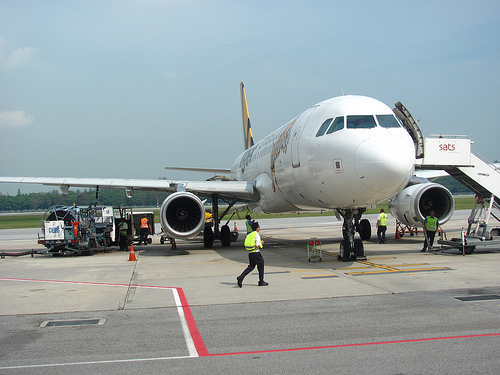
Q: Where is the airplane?
A: On the tarmac.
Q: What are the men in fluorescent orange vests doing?
A: Loading luggages.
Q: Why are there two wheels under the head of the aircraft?
A: To better control landings on runways.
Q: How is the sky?
A: Hazy.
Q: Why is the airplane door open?
A: Because it is still on the ground.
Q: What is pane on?
A: Tarmac.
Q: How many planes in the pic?
A: 1.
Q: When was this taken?
A: During the day.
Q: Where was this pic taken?
A: At the airport.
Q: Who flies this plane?
A: A pilot.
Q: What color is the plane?
A: White.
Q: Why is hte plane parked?
A: Loading or unloading luggage.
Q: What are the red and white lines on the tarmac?
A: Parking lanes.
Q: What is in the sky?
A: Clouds.